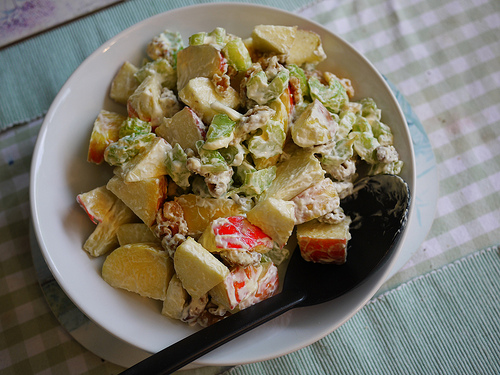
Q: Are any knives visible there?
A: No, there are no knives.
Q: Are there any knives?
A: No, there are no knives.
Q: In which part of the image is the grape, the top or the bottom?
A: The grape is in the top of the image.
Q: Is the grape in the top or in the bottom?
A: The grape is in the top of the image.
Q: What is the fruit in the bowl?
A: The fruit is a grape.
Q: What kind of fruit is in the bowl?
A: The fruit is a grape.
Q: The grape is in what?
A: The grape is in the bowl.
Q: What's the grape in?
A: The grape is in the bowl.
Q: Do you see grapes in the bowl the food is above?
A: Yes, there is a grape in the bowl.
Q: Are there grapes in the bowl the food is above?
A: Yes, there is a grape in the bowl.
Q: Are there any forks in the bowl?
A: No, there is a grape in the bowl.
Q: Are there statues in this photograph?
A: No, there are no statues.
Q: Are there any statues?
A: No, there are no statues.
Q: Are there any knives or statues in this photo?
A: No, there are no statues or knives.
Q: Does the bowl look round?
A: Yes, the bowl is round.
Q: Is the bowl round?
A: Yes, the bowl is round.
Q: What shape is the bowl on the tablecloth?
A: The bowl is round.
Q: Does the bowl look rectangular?
A: No, the bowl is round.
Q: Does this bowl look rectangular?
A: No, the bowl is round.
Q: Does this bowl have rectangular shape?
A: No, the bowl is round.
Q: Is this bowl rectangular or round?
A: The bowl is round.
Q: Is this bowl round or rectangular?
A: The bowl is round.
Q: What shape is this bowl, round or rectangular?
A: The bowl is round.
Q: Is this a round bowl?
A: Yes, this is a round bowl.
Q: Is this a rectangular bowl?
A: No, this is a round bowl.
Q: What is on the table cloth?
A: The bowl is on the table cloth.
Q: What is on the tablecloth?
A: The bowl is on the table cloth.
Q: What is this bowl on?
A: The bowl is on the tablecloth.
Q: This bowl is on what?
A: The bowl is on the tablecloth.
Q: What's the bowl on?
A: The bowl is on the tablecloth.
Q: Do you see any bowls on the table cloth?
A: Yes, there is a bowl on the table cloth.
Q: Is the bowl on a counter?
A: No, the bowl is on a tablecloth.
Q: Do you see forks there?
A: No, there are no forks.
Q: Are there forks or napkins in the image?
A: No, there are no forks or napkins.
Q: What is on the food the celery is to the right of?
A: The dressing is on the food.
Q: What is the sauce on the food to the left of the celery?
A: The sauce is a dressing.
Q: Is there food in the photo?
A: Yes, there is food.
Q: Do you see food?
A: Yes, there is food.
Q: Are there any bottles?
A: No, there are no bottles.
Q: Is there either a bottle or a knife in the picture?
A: No, there are no bottles or knives.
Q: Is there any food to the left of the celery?
A: Yes, there is food to the left of the celery.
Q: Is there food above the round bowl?
A: Yes, there is food above the bowl.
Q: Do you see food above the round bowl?
A: Yes, there is food above the bowl.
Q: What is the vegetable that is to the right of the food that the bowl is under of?
A: The vegetable is a celery.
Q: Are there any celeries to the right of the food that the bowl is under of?
A: Yes, there is a celery to the right of the food.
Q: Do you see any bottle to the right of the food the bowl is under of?
A: No, there is a celery to the right of the food.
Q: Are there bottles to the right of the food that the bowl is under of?
A: No, there is a celery to the right of the food.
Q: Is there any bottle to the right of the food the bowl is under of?
A: No, there is a celery to the right of the food.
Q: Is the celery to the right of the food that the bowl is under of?
A: Yes, the celery is to the right of the food.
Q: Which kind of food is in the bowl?
A: The food is a pecan.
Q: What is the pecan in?
A: The pecan is in the bowl.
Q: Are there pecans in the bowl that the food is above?
A: Yes, there is a pecan in the bowl.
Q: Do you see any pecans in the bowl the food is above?
A: Yes, there is a pecan in the bowl.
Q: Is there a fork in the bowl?
A: No, there is a pecan in the bowl.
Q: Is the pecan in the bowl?
A: Yes, the pecan is in the bowl.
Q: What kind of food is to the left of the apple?
A: The food is a pecan.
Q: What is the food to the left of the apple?
A: The food is a pecan.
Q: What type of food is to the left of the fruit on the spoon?
A: The food is a pecan.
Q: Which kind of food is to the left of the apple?
A: The food is a pecan.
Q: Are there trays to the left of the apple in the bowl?
A: No, there is a pecan to the left of the apple.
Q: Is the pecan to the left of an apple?
A: Yes, the pecan is to the left of an apple.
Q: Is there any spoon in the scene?
A: Yes, there is a spoon.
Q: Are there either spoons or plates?
A: Yes, there is a spoon.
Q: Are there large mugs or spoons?
A: Yes, there is a large spoon.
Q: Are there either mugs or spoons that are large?
A: Yes, the spoon is large.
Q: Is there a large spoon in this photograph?
A: Yes, there is a large spoon.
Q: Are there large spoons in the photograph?
A: Yes, there is a large spoon.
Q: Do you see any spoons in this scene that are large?
A: Yes, there is a large spoon.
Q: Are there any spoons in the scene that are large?
A: Yes, there is a spoon that is large.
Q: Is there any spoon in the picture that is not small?
A: Yes, there is a large spoon.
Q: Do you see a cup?
A: No, there are no cups.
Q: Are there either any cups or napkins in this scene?
A: No, there are no cups or napkins.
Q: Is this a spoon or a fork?
A: This is a spoon.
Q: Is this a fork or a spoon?
A: This is a spoon.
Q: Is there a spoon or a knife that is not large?
A: No, there is a spoon but it is large.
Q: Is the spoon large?
A: Yes, the spoon is large.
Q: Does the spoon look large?
A: Yes, the spoon is large.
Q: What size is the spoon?
A: The spoon is large.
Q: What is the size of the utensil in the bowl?
A: The spoon is large.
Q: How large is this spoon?
A: The spoon is large.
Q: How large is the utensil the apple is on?
A: The spoon is large.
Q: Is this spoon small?
A: No, the spoon is large.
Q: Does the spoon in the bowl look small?
A: No, the spoon is large.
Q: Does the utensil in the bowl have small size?
A: No, the spoon is large.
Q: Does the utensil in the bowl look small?
A: No, the spoon is large.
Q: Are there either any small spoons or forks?
A: No, there is a spoon but it is large.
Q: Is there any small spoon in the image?
A: No, there is a spoon but it is large.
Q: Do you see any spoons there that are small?
A: No, there is a spoon but it is large.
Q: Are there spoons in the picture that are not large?
A: No, there is a spoon but it is large.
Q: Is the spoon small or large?
A: The spoon is large.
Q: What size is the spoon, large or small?
A: The spoon is large.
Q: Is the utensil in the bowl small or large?
A: The spoon is large.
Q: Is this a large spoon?
A: Yes, this is a large spoon.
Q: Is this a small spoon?
A: No, this is a large spoon.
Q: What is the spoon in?
A: The spoon is in the bowl.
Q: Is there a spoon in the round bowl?
A: Yes, there is a spoon in the bowl.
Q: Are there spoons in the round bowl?
A: Yes, there is a spoon in the bowl.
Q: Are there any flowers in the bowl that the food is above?
A: No, there is a spoon in the bowl.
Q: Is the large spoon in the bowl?
A: Yes, the spoon is in the bowl.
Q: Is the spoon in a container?
A: No, the spoon is in the bowl.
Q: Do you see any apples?
A: Yes, there is an apple.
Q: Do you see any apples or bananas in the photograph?
A: Yes, there is an apple.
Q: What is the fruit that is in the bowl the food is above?
A: The fruit is an apple.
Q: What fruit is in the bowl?
A: The fruit is an apple.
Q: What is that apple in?
A: The apple is in the bowl.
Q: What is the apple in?
A: The apple is in the bowl.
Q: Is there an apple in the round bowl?
A: Yes, there is an apple in the bowl.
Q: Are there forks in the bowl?
A: No, there is an apple in the bowl.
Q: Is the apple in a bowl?
A: Yes, the apple is in a bowl.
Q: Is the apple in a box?
A: No, the apple is in a bowl.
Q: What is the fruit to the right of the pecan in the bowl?
A: The fruit is an apple.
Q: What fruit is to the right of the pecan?
A: The fruit is an apple.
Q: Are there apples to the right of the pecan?
A: Yes, there is an apple to the right of the pecan.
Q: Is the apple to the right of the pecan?
A: Yes, the apple is to the right of the pecan.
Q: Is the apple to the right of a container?
A: No, the apple is to the right of the pecan.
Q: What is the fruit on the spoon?
A: The fruit is an apple.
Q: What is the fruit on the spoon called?
A: The fruit is an apple.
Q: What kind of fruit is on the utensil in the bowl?
A: The fruit is an apple.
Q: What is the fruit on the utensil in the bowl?
A: The fruit is an apple.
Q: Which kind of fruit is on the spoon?
A: The fruit is an apple.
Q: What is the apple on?
A: The apple is on the spoon.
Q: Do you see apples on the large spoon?
A: Yes, there is an apple on the spoon.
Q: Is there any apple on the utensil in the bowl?
A: Yes, there is an apple on the spoon.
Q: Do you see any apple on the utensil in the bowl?
A: Yes, there is an apple on the spoon.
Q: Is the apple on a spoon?
A: Yes, the apple is on a spoon.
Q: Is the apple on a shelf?
A: No, the apple is on a spoon.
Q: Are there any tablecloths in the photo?
A: Yes, there is a tablecloth.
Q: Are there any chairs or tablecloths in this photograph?
A: Yes, there is a tablecloth.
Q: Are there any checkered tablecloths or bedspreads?
A: Yes, there is a checkered tablecloth.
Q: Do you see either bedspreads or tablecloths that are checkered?
A: Yes, the tablecloth is checkered.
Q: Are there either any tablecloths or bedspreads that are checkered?
A: Yes, the tablecloth is checkered.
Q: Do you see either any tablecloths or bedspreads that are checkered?
A: Yes, the tablecloth is checkered.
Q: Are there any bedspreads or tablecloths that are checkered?
A: Yes, the tablecloth is checkered.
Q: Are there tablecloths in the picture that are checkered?
A: Yes, there is a checkered tablecloth.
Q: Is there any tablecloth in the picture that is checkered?
A: Yes, there is a tablecloth that is checkered.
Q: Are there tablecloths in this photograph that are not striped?
A: Yes, there is a checkered tablecloth.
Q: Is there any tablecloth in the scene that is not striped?
A: Yes, there is a checkered tablecloth.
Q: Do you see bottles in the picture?
A: No, there are no bottles.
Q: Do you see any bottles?
A: No, there are no bottles.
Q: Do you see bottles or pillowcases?
A: No, there are no bottles or pillowcases.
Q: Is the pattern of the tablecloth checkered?
A: Yes, the tablecloth is checkered.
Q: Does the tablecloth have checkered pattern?
A: Yes, the tablecloth is checkered.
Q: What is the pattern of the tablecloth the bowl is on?
A: The tablecloth is checkered.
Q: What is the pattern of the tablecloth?
A: The tablecloth is checkered.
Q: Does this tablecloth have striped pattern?
A: No, the tablecloth is checkered.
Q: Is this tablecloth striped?
A: No, the tablecloth is checkered.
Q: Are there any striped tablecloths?
A: No, there is a tablecloth but it is checkered.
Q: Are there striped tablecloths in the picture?
A: No, there is a tablecloth but it is checkered.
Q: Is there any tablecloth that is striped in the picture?
A: No, there is a tablecloth but it is checkered.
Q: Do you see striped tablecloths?
A: No, there is a tablecloth but it is checkered.